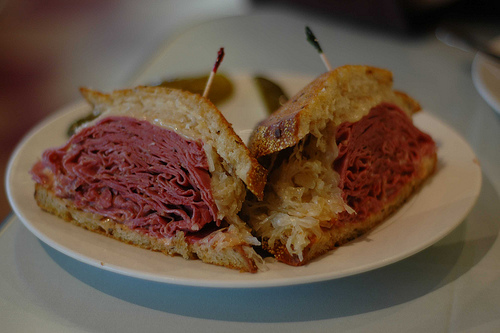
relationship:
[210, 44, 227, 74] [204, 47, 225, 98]
plastic on toothpick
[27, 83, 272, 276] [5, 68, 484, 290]
sandwhich served on plate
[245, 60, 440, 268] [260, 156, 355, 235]
sandwhich has sauerkraut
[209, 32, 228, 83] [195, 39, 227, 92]
plastic on toothpick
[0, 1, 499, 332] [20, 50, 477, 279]
table on sandwiches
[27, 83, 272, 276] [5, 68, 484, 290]
sandwhich on plate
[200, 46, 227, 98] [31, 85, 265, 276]
tooth pick sticking out of sandwich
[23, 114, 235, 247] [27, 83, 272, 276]
ham between sandwhich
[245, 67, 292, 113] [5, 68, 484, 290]
pickle on plate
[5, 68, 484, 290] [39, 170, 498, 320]
plate casting shadow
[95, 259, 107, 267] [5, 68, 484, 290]
speck on edge of plate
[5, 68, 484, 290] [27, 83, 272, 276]
plate has sandwhich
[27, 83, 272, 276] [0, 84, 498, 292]
sandwhich on plate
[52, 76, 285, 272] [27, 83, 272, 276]
sandwhich has sandwhich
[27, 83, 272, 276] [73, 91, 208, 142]
sandwhich has swiss cheese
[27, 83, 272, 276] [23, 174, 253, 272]
sandwhich has bread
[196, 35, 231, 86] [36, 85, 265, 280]
tooth pick sticking out of sandwhich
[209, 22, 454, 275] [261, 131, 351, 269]
sandwhich has saurkraut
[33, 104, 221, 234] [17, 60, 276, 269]
ham in sandwich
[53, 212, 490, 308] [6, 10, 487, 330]
shadow on table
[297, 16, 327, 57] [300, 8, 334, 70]
wrapper on toothpick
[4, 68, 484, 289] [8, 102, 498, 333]
plate on table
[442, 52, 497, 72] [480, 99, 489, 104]
utensil on plate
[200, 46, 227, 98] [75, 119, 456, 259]
tooth pick holding together a sandwich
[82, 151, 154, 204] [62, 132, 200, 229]
corned beef in sandwich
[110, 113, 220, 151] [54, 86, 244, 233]
swiss cheese in sandwich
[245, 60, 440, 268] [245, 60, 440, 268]
sandwhich made with sandwhich